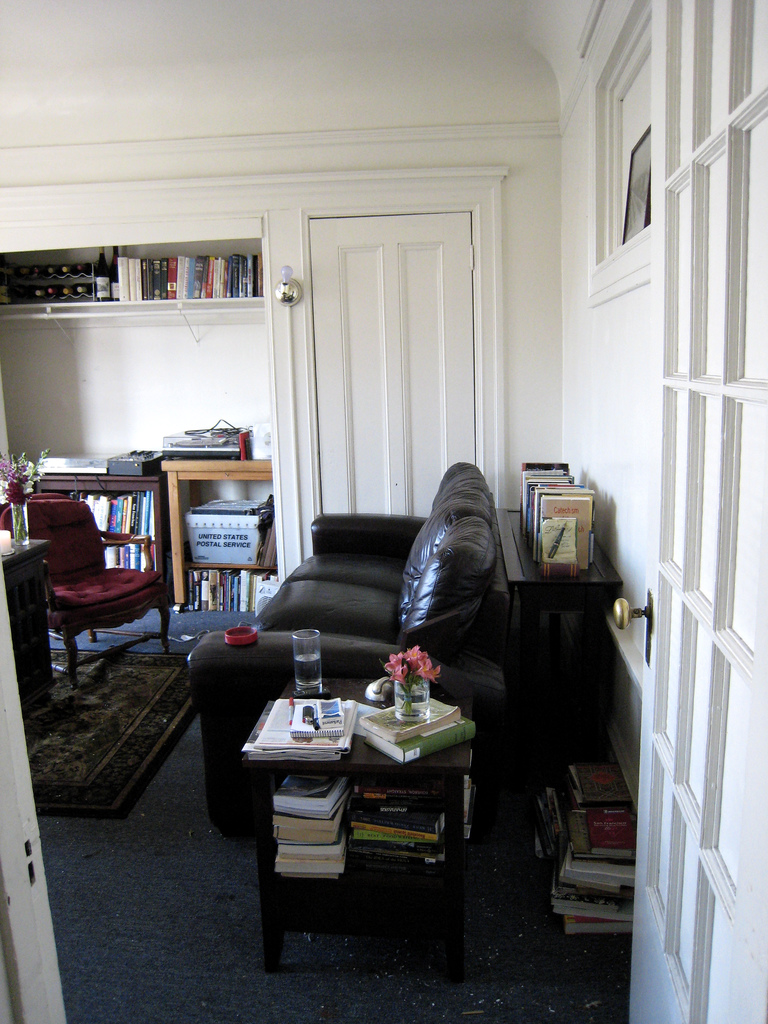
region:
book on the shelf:
[269, 780, 330, 814]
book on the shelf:
[287, 814, 326, 828]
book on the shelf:
[291, 829, 321, 845]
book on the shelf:
[351, 827, 391, 845]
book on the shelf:
[559, 827, 625, 859]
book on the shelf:
[562, 859, 619, 878]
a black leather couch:
[188, 462, 505, 838]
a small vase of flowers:
[384, 648, 441, 720]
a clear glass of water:
[291, 625, 323, 693]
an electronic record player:
[161, 433, 241, 461]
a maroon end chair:
[25, 492, 173, 691]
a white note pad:
[289, 696, 346, 738]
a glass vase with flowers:
[0, 446, 48, 544]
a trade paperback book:
[360, 693, 462, 744]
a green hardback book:
[363, 710, 474, 763]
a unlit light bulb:
[279, 261, 293, 285]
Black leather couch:
[181, 449, 505, 848]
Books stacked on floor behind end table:
[522, 746, 640, 946]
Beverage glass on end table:
[284, 617, 331, 701]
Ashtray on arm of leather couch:
[216, 618, 263, 655]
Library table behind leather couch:
[494, 497, 626, 746]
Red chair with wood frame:
[0, 474, 183, 690]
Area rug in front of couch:
[5, 640, 212, 828]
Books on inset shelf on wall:
[8, 240, 276, 312]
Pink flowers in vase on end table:
[376, 633, 442, 729]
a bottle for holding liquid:
[86, 248, 113, 309]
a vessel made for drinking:
[284, 617, 330, 692]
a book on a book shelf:
[137, 492, 155, 535]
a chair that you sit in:
[27, 475, 177, 663]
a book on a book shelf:
[87, 497, 107, 534]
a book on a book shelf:
[104, 496, 118, 532]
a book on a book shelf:
[113, 489, 128, 537]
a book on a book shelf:
[120, 491, 129, 535]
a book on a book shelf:
[130, 496, 138, 539]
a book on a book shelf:
[138, 497, 150, 548]